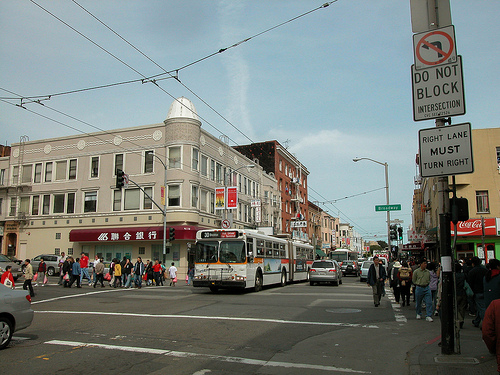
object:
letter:
[96, 232, 111, 242]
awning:
[68, 226, 212, 241]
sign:
[373, 204, 402, 212]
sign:
[447, 215, 500, 238]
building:
[410, 125, 500, 265]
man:
[410, 260, 436, 321]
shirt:
[411, 266, 432, 285]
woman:
[33, 257, 49, 286]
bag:
[31, 270, 40, 284]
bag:
[41, 272, 51, 287]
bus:
[192, 225, 317, 291]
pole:
[384, 160, 392, 256]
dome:
[161, 97, 204, 125]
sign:
[411, 24, 454, 70]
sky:
[0, 2, 500, 243]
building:
[1, 95, 277, 284]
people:
[21, 258, 37, 297]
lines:
[32, 309, 381, 328]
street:
[1, 271, 499, 374]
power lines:
[69, 0, 369, 232]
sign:
[410, 56, 467, 121]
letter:
[110, 230, 119, 244]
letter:
[122, 232, 132, 243]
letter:
[135, 230, 145, 242]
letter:
[147, 228, 158, 240]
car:
[307, 257, 344, 286]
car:
[336, 260, 364, 277]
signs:
[415, 123, 476, 177]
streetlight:
[388, 222, 397, 229]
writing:
[96, 229, 157, 241]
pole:
[433, 2, 456, 355]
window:
[474, 190, 491, 215]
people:
[366, 255, 386, 307]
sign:
[213, 185, 227, 213]